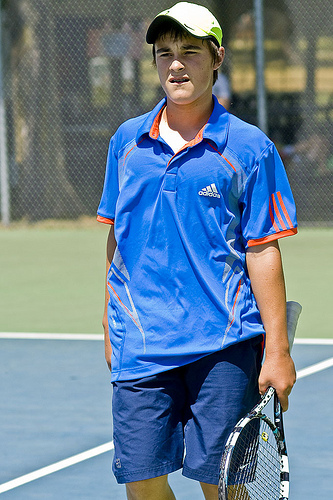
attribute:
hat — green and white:
[146, 0, 224, 53]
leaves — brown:
[4, 205, 113, 230]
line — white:
[290, 351, 329, 382]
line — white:
[16, 435, 106, 494]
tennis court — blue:
[1, 312, 106, 417]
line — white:
[29, 324, 69, 345]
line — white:
[299, 358, 320, 382]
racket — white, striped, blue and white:
[201, 301, 313, 499]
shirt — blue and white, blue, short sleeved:
[95, 97, 298, 382]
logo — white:
[196, 181, 218, 196]